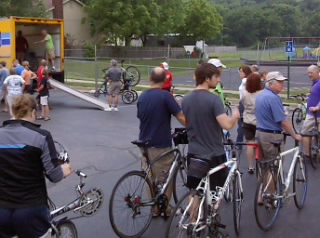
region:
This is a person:
[3, 90, 73, 236]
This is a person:
[134, 66, 192, 221]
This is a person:
[181, 49, 239, 219]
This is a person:
[259, 69, 288, 212]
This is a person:
[243, 71, 264, 156]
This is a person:
[296, 61, 319, 168]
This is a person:
[103, 56, 132, 127]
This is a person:
[37, 70, 58, 118]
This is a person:
[21, 48, 37, 107]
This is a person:
[37, 27, 63, 74]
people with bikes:
[0, 46, 312, 237]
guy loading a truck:
[10, 15, 67, 69]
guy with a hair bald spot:
[132, 60, 179, 182]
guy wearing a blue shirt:
[131, 64, 179, 181]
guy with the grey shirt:
[183, 62, 235, 184]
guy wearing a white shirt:
[251, 68, 293, 169]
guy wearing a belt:
[252, 66, 298, 188]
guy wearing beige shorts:
[249, 69, 292, 189]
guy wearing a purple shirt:
[294, 59, 319, 161]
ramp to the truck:
[1, 11, 122, 117]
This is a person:
[0, 54, 12, 110]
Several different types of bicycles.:
[22, 41, 313, 228]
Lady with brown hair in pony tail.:
[0, 89, 83, 233]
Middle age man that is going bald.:
[133, 57, 186, 212]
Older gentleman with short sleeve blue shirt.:
[251, 64, 300, 211]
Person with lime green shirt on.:
[194, 51, 232, 127]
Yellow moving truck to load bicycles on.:
[4, 14, 65, 92]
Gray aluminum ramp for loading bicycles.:
[47, 74, 114, 112]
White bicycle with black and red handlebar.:
[173, 135, 264, 234]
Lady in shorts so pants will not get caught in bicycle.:
[4, 95, 74, 234]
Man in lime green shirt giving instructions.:
[32, 27, 58, 70]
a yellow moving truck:
[1, 12, 78, 92]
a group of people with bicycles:
[8, 47, 314, 237]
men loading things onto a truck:
[7, 22, 96, 88]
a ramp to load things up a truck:
[41, 70, 115, 124]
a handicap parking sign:
[282, 37, 296, 100]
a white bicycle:
[250, 139, 319, 224]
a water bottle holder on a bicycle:
[209, 184, 228, 210]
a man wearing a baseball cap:
[265, 62, 293, 96]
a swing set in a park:
[259, 32, 316, 58]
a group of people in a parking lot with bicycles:
[9, 64, 318, 227]